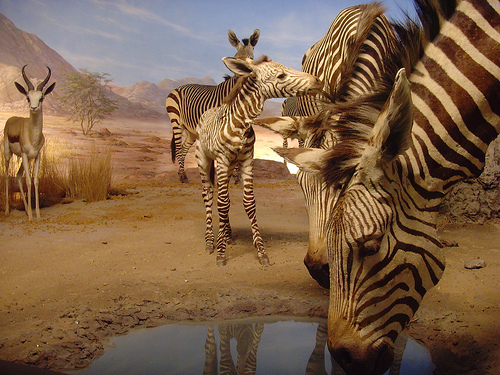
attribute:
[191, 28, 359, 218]
zebra — standing, drinking, here, beige, striped, baby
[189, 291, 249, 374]
shadow — failing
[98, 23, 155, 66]
sky — blue, reflecting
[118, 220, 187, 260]
sand — around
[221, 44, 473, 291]
zebras — here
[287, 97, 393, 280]
animals — around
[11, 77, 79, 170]
antelope — thin, facing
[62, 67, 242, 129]
range — background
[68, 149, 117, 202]
grass — tall, dry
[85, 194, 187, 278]
ground — brown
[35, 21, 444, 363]
display — museum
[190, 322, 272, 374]
pond — shallow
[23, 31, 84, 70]
mountain — distant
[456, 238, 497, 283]
rock — here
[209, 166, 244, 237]
leg — tall